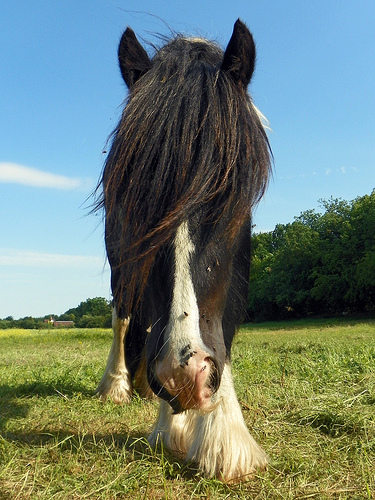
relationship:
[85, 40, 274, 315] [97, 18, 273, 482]
mane of horse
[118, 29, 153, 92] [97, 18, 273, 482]
ear of horse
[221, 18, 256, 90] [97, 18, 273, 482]
ear of horse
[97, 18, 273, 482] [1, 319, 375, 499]
horse in field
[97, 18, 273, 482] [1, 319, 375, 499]
horse eating in field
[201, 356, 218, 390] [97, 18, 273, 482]
nostril of horse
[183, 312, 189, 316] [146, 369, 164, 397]
fly on nostril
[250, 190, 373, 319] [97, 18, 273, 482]
trees beside horse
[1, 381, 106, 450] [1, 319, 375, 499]
shadow on field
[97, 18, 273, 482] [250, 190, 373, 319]
horse besides some trees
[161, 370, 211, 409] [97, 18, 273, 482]
nose of horse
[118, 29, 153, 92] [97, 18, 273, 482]
ear on horse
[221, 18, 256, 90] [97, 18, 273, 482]
ear on horse